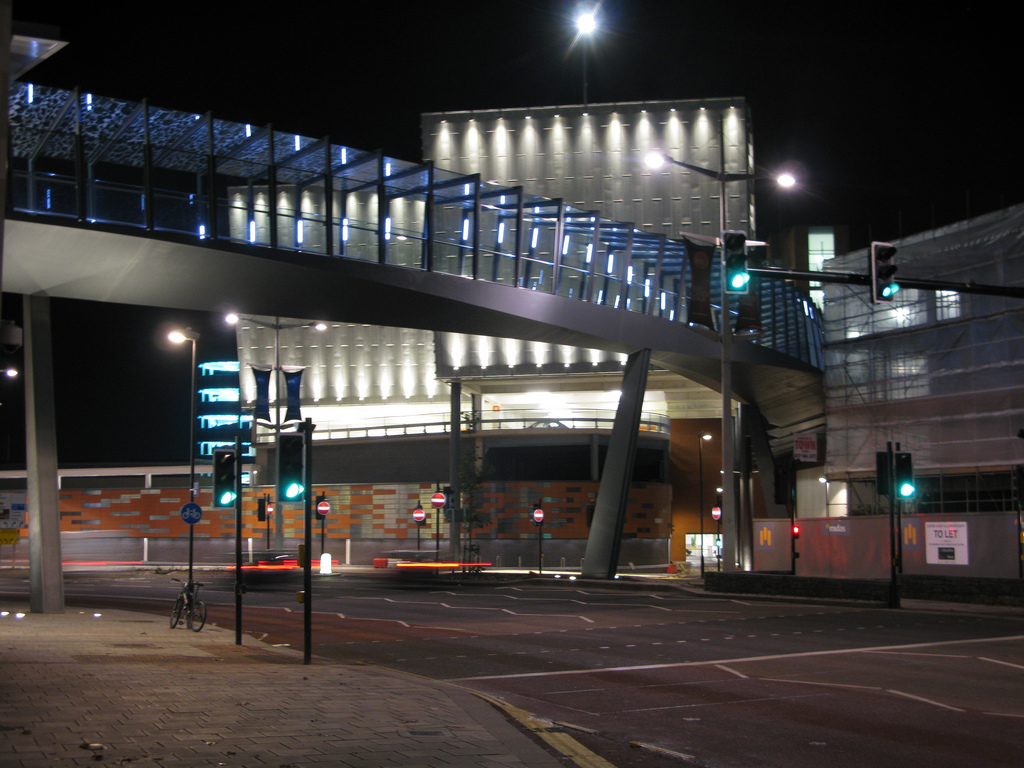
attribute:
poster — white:
[915, 516, 973, 584]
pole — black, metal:
[298, 421, 327, 668]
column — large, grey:
[712, 361, 752, 574]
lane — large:
[311, 615, 482, 666]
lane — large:
[362, 593, 476, 639]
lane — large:
[449, 590, 555, 614]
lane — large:
[545, 583, 621, 612]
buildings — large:
[819, 248, 1013, 504]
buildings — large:
[241, 103, 747, 471]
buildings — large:
[228, 314, 554, 428]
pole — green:
[756, 261, 867, 285]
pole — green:
[882, 497, 917, 603]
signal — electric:
[876, 449, 919, 617]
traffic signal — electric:
[873, 444, 960, 514]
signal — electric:
[207, 433, 312, 514]